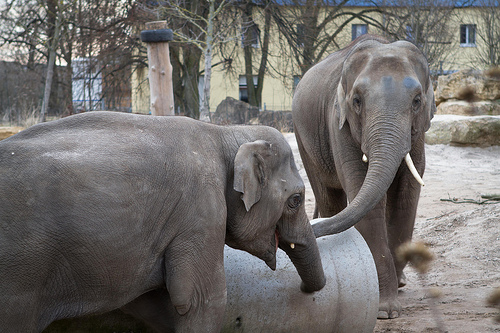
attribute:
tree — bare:
[390, 18, 471, 82]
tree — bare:
[230, 19, 272, 94]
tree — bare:
[466, 10, 499, 71]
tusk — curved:
[400, 151, 432, 196]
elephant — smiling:
[146, 121, 451, 268]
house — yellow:
[130, 0, 488, 111]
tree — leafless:
[144, 0, 265, 134]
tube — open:
[202, 212, 382, 332]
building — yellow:
[177, 18, 499, 110]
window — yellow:
[456, 23, 477, 47]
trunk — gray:
[305, 113, 413, 240]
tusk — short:
[400, 154, 423, 185]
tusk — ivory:
[390, 147, 428, 204]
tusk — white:
[407, 154, 427, 188]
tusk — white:
[359, 153, 366, 161]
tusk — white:
[289, 242, 294, 250]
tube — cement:
[161, 216, 384, 331]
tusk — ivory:
[286, 239, 298, 254]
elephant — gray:
[285, 40, 452, 285]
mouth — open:
[274, 225, 293, 267]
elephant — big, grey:
[0, 112, 324, 331]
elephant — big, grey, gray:
[287, 36, 436, 319]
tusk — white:
[360, 153, 424, 187]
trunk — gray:
[284, 225, 332, 302]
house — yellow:
[203, 9, 493, 103]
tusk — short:
[289, 241, 295, 248]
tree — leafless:
[233, 1, 276, 111]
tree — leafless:
[272, 1, 409, 106]